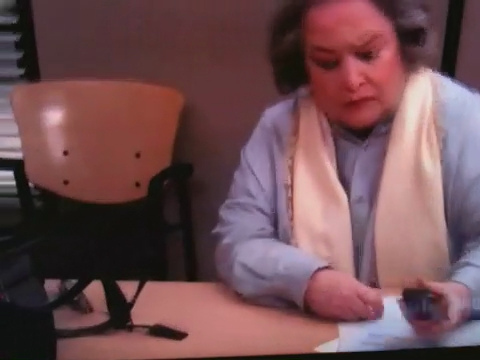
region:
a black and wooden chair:
[0, 79, 191, 278]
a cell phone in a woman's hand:
[397, 281, 466, 339]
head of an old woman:
[262, 0, 429, 137]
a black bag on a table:
[2, 210, 185, 359]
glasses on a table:
[57, 279, 93, 311]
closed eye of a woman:
[354, 44, 378, 65]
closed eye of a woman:
[312, 50, 341, 70]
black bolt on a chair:
[133, 151, 140, 160]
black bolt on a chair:
[133, 178, 139, 190]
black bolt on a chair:
[61, 177, 71, 187]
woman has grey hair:
[260, 2, 439, 60]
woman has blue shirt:
[244, 54, 479, 352]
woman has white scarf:
[246, 85, 466, 311]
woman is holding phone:
[384, 260, 446, 345]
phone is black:
[377, 280, 466, 330]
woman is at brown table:
[157, 289, 256, 358]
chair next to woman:
[11, 96, 188, 267]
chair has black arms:
[11, 169, 203, 284]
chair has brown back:
[15, 64, 165, 187]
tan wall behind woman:
[160, 13, 247, 98]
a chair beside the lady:
[11, 68, 197, 271]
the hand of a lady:
[317, 260, 389, 334]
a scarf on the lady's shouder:
[282, 121, 358, 245]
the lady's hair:
[257, 13, 295, 97]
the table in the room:
[193, 291, 248, 358]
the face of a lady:
[285, 4, 412, 136]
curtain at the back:
[55, 10, 237, 63]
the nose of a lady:
[340, 74, 371, 91]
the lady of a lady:
[307, 38, 345, 74]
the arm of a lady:
[194, 101, 279, 314]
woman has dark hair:
[242, 0, 445, 74]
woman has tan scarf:
[271, 88, 476, 261]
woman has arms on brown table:
[172, 290, 311, 355]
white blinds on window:
[1, 11, 31, 149]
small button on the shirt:
[354, 190, 364, 206]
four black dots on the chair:
[51, 140, 149, 196]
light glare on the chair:
[34, 96, 68, 154]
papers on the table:
[295, 276, 478, 350]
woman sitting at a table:
[211, 3, 479, 345]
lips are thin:
[339, 88, 382, 111]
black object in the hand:
[393, 269, 470, 334]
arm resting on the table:
[213, 242, 396, 328]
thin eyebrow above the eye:
[351, 33, 387, 65]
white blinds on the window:
[1, 1, 62, 214]